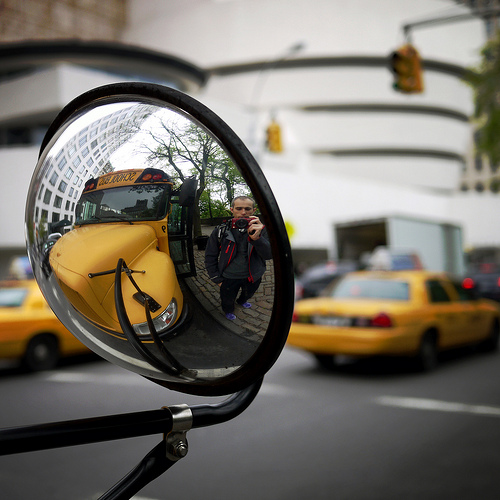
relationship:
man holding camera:
[207, 192, 269, 326] [227, 218, 249, 239]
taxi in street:
[281, 264, 499, 371] [1, 336, 492, 495]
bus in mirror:
[44, 164, 200, 338] [18, 85, 291, 393]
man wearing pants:
[207, 192, 269, 326] [220, 277, 267, 311]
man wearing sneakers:
[207, 192, 269, 326] [224, 299, 260, 324]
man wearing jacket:
[207, 192, 269, 326] [207, 222, 273, 285]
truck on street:
[331, 214, 469, 278] [1, 336, 492, 495]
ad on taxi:
[377, 244, 427, 274] [281, 264, 499, 371]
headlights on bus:
[129, 301, 180, 343] [44, 164, 200, 338]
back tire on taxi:
[410, 329, 447, 370] [281, 264, 499, 371]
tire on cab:
[27, 330, 64, 369] [0, 271, 80, 370]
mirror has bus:
[18, 85, 291, 393] [44, 164, 200, 338]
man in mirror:
[207, 192, 269, 326] [18, 85, 291, 393]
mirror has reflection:
[18, 85, 291, 393] [42, 134, 263, 357]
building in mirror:
[48, 98, 153, 247] [18, 85, 291, 393]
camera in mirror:
[227, 218, 249, 239] [18, 85, 291, 393]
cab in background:
[0, 271, 80, 370] [5, 11, 495, 375]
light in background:
[392, 44, 420, 91] [5, 11, 495, 375]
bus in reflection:
[44, 164, 200, 338] [42, 134, 263, 357]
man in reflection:
[207, 192, 269, 326] [42, 134, 263, 357]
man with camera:
[207, 192, 269, 326] [227, 218, 249, 239]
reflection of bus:
[42, 134, 263, 357] [44, 164, 200, 338]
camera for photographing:
[227, 218, 249, 239] [207, 192, 269, 326]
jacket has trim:
[207, 222, 273, 285] [222, 240, 236, 258]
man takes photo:
[207, 192, 269, 326] [94, 164, 283, 340]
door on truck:
[340, 216, 390, 270] [331, 214, 469, 278]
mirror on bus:
[18, 85, 291, 393] [44, 164, 200, 338]